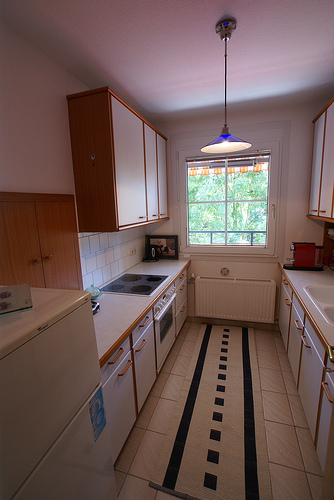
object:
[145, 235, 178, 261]
frame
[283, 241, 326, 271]
appliance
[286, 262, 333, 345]
countertop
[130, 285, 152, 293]
burner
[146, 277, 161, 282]
burner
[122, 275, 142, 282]
burner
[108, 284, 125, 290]
burner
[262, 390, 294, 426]
tiles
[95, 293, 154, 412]
cabinet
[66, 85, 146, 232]
cabinets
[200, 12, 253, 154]
light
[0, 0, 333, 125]
ceiling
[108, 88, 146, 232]
cabinet door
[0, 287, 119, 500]
freezer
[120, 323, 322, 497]
floor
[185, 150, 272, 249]
window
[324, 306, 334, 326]
sink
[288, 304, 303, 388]
door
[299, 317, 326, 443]
door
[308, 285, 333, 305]
basin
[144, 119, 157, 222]
cabinets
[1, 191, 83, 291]
cabinet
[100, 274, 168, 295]
stove top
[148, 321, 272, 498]
rug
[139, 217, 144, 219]
knobs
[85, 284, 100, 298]
glass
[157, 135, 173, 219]
cabinets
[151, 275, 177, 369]
oven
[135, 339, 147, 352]
handle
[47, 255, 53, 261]
door knob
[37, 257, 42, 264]
door knob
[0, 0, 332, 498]
kitchen